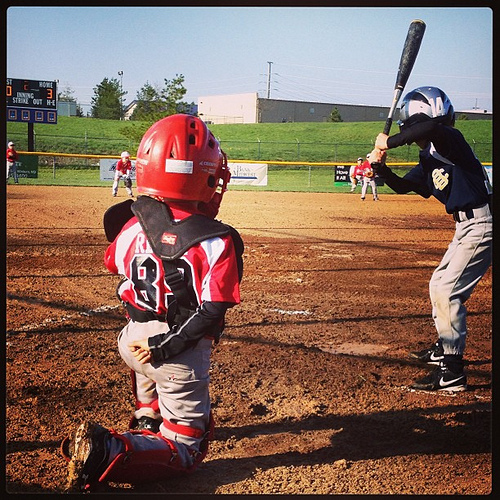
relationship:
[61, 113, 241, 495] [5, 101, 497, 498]
people on field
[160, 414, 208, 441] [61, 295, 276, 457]
stripe on pants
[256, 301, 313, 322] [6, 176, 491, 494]
white line on ground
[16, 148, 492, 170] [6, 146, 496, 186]
yellow border on top of fence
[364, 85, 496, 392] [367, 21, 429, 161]
person holding bat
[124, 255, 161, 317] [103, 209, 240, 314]
number on jersey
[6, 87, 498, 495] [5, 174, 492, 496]
people playing on earth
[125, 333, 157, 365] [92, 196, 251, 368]
hand behind back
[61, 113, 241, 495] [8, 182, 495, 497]
people kneeling in dirt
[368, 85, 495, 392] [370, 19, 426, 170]
person playing bat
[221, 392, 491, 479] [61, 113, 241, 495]
shadow from people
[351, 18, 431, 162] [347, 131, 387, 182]
bat in hands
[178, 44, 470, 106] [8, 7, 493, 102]
power lines are in sky